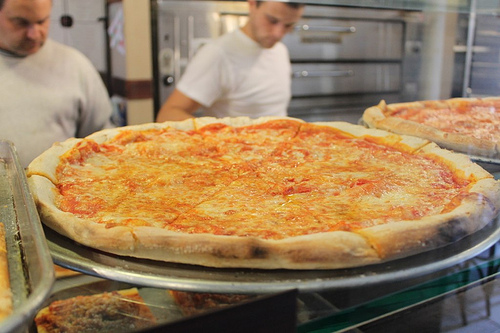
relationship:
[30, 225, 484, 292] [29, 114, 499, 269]
pan under pizza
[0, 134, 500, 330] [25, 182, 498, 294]
shelf holding pan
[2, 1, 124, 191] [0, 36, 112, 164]
man in a shirt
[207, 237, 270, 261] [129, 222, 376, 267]
burn marks on a crust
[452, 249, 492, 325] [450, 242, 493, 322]
legs of a chair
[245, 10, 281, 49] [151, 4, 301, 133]
beard on a man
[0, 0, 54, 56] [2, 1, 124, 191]
head of a man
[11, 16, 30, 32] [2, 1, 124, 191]
eye on a man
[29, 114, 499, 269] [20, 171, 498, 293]
pizza sitting on a tray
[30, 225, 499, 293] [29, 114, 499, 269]
pan with a pizza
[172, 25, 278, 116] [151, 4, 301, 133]
t-shirt on man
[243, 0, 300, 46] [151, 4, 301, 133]
head of a man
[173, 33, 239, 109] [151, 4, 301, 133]
shoulder of a man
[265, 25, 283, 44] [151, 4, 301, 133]
nose on man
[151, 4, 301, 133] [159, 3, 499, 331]
man on left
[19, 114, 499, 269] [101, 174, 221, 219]
pizza with cheese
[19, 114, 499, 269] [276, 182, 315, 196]
pizza with sauce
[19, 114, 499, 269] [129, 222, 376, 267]
pizza with crust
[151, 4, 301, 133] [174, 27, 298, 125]
man in tshirt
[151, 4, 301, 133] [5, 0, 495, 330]
man working in kitchen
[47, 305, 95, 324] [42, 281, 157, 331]
sauce covered slice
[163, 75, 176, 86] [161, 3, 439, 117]
knob on oven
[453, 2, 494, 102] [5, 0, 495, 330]
trays in kitchen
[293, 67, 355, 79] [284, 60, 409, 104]
handle on door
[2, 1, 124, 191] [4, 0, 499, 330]
man working in pizzaria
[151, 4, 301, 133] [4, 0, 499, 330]
man working in pizzaria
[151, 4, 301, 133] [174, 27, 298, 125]
man wearing tshirt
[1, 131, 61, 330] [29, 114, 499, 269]
pan for cooking pizza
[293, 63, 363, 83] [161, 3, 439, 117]
handle of oven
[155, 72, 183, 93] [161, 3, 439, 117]
knob on oven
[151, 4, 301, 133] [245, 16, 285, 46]
man with hair